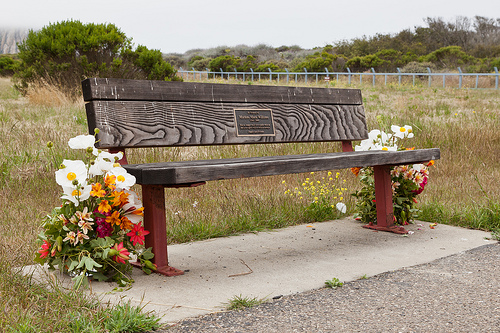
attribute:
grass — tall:
[0, 85, 498, 331]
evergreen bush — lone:
[4, 19, 187, 94]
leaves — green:
[61, 244, 165, 286]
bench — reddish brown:
[81, 77, 440, 277]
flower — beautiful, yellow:
[49, 136, 154, 258]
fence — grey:
[177, 65, 499, 88]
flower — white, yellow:
[25, 132, 182, 304]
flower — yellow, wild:
[292, 183, 307, 208]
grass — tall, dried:
[0, 88, 459, 250]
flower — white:
[334, 201, 347, 215]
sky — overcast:
[90, 0, 484, 67]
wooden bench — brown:
[87, 81, 437, 237]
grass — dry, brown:
[409, 113, 497, 205]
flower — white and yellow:
[49, 144, 110, 222]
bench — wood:
[77, 78, 368, 145]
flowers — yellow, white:
[405, 162, 427, 196]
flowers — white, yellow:
[43, 113, 151, 264]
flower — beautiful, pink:
[18, 161, 148, 265]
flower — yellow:
[91, 182, 140, 218]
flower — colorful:
[65, 133, 94, 153]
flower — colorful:
[123, 219, 148, 244]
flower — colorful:
[85, 181, 106, 200]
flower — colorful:
[98, 173, 116, 190]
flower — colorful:
[36, 235, 48, 259]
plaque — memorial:
[234, 107, 276, 137]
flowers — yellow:
[334, 175, 343, 182]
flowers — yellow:
[337, 186, 345, 193]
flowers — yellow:
[301, 175, 308, 183]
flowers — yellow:
[289, 188, 298, 193]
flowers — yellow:
[329, 202, 334, 209]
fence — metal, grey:
[174, 62, 499, 84]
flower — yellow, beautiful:
[87, 183, 107, 198]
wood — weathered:
[78, 72, 442, 187]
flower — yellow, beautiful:
[56, 152, 118, 194]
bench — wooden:
[78, 75, 442, 185]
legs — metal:
[128, 166, 411, 278]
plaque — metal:
[234, 108, 276, 135]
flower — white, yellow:
[58, 158, 84, 188]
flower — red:
[38, 243, 55, 261]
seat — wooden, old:
[77, 77, 444, 272]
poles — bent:
[176, 62, 485, 89]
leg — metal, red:
[140, 180, 186, 274]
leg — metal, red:
[362, 164, 410, 233]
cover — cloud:
[88, 6, 475, 77]